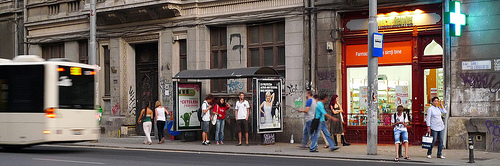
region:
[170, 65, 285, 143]
Bus stop with a black roof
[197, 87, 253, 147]
Three people waiting in a bus stop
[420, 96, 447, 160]
Woman holding a blue and white bag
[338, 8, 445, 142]
Red and orange store front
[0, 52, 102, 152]
Back end of a white bus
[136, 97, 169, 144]
Backs of two women walking together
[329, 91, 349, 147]
Woman looking in a store window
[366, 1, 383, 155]
Tall grey metal pole with a blue sign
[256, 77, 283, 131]
Advertisement with a picture of a woman in white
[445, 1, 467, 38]
Lighted cross on the side of a building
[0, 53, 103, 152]
A bus is driving on the street.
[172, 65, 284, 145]
People stand under the stop shelter.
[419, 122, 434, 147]
A woman holds a bag.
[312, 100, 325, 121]
The shirt is blue.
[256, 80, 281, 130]
A poster is on the shelter.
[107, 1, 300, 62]
A building is behind the bus stop.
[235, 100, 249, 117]
The shirt is white.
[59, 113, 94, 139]
The bus is white.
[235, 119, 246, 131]
The shorts are black.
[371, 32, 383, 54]
a blue and white sign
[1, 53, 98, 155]
the back of a moving bus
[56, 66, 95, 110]
the back windshield of a bus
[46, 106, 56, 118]
the back brake light of a bus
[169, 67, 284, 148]
a gray bus stop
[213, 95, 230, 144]
a woman in a red sweater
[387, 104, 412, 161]
a man carrying a backpack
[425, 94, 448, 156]
a woman talking on a cell phone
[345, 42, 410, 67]
an orange banner over a store front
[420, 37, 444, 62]
a white light globe over a doorway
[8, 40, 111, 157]
a black and white bus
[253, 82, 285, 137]
a woman on a poster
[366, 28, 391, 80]
a blue and white sign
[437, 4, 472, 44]
a glowing plus sign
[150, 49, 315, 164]
a shelter for bus patrons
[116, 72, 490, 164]
several people walking on the sidewalk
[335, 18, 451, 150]
a red store front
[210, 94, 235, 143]
a girl in red shirt and jeans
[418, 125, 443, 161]
a white and blue bag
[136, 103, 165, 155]
a green top with white pants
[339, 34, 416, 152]
an orange store front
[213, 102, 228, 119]
a red shirt on a woman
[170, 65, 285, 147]
a bus stop by the street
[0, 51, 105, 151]
a white bus on aroad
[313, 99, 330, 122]
a blue shirt on a person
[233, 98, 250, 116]
a white shirt on a man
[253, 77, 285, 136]
an advertisement at a bus stop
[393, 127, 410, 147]
faded denim shorts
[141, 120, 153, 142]
white pants on a woman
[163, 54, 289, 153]
Bus stop by a road.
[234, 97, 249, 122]
White shirt on a man.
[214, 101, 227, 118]
Red shirt on a woman.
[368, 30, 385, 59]
Blue sign on a pole.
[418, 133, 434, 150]
Bag in a person's hand.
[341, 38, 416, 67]
Orange sign on a store.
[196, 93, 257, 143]
People standing at a bus stop.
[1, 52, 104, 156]
Bus on a street.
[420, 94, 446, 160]
woman carrying a bag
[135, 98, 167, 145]
two women walking on the sidewalk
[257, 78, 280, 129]
advertisement on the bus stop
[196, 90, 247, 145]
three people standing on the bus stop